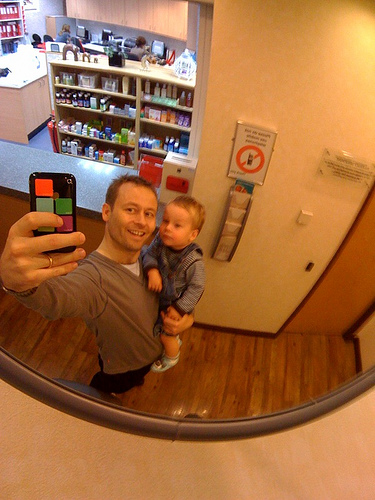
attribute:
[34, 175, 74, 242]
blocks — colored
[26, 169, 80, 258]
phone — smart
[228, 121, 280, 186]
sign — prohibiting phones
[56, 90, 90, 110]
bottles — for prescribed meds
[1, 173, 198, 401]
man — taking a selfie, at the pharmacy, taking a picture, smiling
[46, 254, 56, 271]
ring — a wedding ring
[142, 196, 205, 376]
boy — little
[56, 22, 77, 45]
person — sitting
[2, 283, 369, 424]
floor — wooden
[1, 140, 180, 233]
countertop — grey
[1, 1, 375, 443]
mirror — for security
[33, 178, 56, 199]
square — orange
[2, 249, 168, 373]
shirt — brown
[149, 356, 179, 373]
shoe — white, blue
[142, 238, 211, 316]
shirt — blue, white, gray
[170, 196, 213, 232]
hair — blonde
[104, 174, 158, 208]
hair — blonde, brown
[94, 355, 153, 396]
pants — black